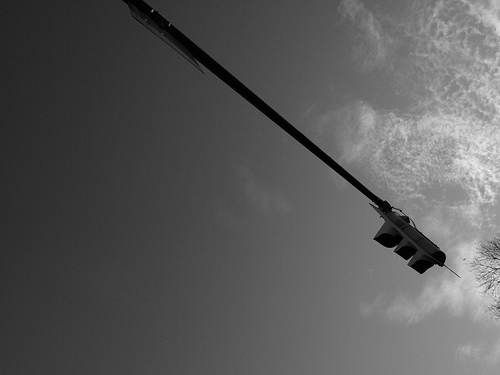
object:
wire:
[393, 207, 416, 229]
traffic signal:
[370, 204, 446, 275]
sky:
[351, 0, 497, 169]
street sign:
[128, 2, 205, 74]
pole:
[123, 0, 394, 213]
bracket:
[145, 7, 156, 20]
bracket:
[163, 20, 173, 35]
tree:
[465, 235, 499, 320]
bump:
[384, 213, 444, 267]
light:
[374, 224, 402, 248]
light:
[394, 237, 417, 260]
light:
[407, 250, 434, 274]